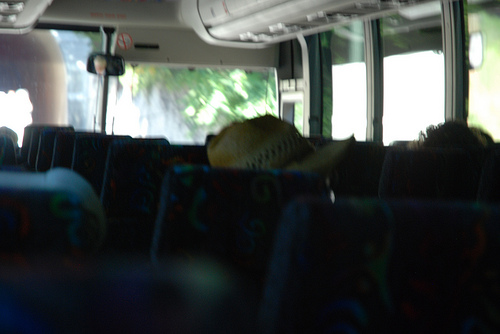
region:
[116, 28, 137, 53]
No smoking sticker at front of bus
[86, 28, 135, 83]
Rear view mirror mounted to front window of bus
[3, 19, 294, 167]
Front windshield of bus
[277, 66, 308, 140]
Top of bus door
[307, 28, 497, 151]
Side windows in bus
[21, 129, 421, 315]
Rows of seats in bus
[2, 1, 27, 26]
Ceiling lights above seats in bus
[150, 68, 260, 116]
Tree branches with green leaves outside of front bus window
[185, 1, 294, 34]
Storage compartment located above seats in bus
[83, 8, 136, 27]
Red lettered sign in bus above rear view mirror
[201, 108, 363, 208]
Person wearing straw hat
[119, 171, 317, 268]
Many multi colored seats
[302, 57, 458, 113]
Windows on the side of bus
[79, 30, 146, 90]
Reflection in rear view mirror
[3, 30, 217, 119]
Large front windshield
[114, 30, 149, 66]
Do not smoke sticker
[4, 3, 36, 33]
Lights on the ceiling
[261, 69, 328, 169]
Bus door in the front right of bus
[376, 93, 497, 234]
People sitting on bus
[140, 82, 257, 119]
Trees outside of bus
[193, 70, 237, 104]
These are green leaves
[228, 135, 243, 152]
This is a hat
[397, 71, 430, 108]
This is the color white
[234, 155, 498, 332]
This is a seat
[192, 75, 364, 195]
This is a hat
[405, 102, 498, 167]
This is brown hair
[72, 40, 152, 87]
This is a rearview mirror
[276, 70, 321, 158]
This is the door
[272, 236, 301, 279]
This is the color blue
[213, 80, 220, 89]
This is the color green.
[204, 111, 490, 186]
people are on a bus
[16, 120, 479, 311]
chairs are in a row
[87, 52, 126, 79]
mirror is on the windshield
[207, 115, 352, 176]
someone is wearing a hat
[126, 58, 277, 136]
trees are in front of bus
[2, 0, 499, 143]
windows are around the bus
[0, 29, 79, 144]
bus is going to go through tunnel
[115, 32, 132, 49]
warning sign near the mirror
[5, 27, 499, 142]
it is sunny outside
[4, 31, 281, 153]
it is bright outside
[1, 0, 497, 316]
passengers are inside a bus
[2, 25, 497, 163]
the bus has windows all around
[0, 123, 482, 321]
the seats are blue on the bus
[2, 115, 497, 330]
passengers are sitting on the bus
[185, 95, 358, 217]
a person has a straw hat on the bus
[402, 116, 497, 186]
a passenger has black hair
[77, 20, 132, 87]
the bus has a rear view mirror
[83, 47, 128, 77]
a reflection of the bus driver is in the rear view mirror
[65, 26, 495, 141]
green trees are outside the bus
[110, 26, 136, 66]
a no smoking sign is on the inside windshield